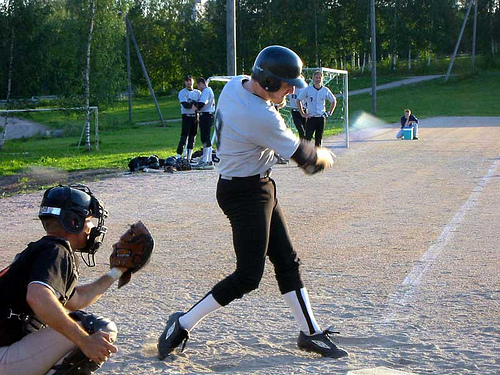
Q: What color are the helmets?
A: Black.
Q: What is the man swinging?
A: Bat.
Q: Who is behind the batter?
A: Catcher.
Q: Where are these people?
A: Baseball field.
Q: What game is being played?
A: Baseball.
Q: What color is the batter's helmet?
A: Black.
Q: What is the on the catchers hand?
A: Baseball mitt.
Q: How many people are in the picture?
A: 7.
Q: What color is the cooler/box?
A: Blue.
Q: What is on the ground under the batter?
A: Sand.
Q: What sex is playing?
A: Males.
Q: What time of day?
A: Afternoon.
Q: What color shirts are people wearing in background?
A: White.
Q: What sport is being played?
A: Baseball.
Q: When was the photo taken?
A: Daytime.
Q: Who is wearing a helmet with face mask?
A: The catcher.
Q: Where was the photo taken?
A: Baseball field.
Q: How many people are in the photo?
A: 7.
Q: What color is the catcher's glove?
A: Brown.